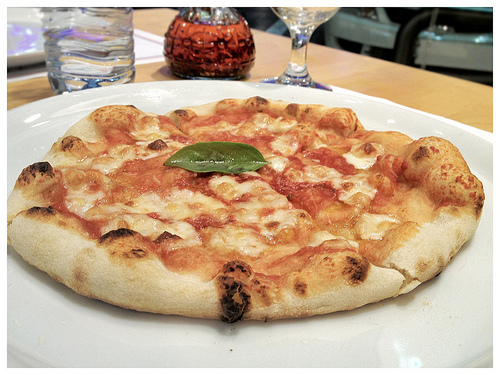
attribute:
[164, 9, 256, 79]
goblet — red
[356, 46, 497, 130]
table — wooden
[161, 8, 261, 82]
bottle — round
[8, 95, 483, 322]
pizza — whole, uneaten, delicious, cheese, cut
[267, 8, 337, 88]
wine glass — clear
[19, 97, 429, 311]
pizza — whole, cheese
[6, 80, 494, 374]
plate — white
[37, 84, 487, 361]
plate — white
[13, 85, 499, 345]
plate — white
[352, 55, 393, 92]
table — wood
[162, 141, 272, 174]
basil leaf — green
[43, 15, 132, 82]
bottle — water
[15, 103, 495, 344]
pizza — small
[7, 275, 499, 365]
plate — large, white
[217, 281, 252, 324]
section — burned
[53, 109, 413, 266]
cheese — melted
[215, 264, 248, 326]
bubble — burst, black